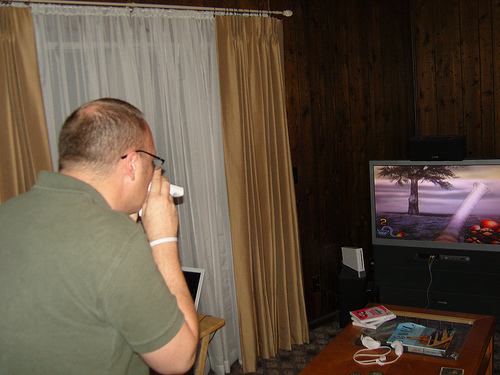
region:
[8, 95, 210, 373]
a man playing wii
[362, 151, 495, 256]
a video game on the TV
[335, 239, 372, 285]
the wii game console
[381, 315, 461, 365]
a closed book on the table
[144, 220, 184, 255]
a white band on wrist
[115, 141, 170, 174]
glasses on the man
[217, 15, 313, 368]
open beige curtains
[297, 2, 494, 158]
dark wood paneled walls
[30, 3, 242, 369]
closed white sheer curtains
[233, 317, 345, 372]
beige and black checkered carpet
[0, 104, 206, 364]
this is a man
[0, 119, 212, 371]
the man is sitted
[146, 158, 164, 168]
the man is wearing spectacles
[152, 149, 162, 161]
the spectacles are back in color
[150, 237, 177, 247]
the man is wearing a wrist band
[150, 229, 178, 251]
the wrist band is white in color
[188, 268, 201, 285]
this is a laptop in front of the man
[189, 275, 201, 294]
the laptop is off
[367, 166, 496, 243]
this is a television screen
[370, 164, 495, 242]
the television screen is on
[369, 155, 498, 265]
The flat screen television.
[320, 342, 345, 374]
The cherry red wood coffee table.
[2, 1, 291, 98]
The white and gold satiny curtains.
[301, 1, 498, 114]
The dark wooden paneled wall.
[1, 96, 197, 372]
A man in a grey shirt.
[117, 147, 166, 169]
The black rimmed glasses.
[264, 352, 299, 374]
The brown designed carpet.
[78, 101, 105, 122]
One small bald spot.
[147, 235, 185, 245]
A white wrist band.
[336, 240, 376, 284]
A video game system.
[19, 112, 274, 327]
man in green shirt playing wii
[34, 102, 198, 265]
man with glasses playing wii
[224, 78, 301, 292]
gold curtains on the window frame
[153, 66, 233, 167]
sheer curtains over night time window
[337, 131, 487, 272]
television screen with game on it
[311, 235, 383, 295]
white box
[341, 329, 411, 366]
wii game controller on table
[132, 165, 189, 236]
wii game controller in man's hand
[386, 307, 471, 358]
magazine on table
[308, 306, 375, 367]
book on brown wooden style table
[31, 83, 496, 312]
a man playing a video game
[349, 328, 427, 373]
a video game controller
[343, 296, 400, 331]
a stack of video games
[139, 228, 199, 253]
a white wrist band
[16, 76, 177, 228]
a man wearing glasses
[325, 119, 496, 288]
a wide screen tv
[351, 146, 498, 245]
a cartoon on tv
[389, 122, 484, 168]
a large black speaker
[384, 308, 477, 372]
a paper back book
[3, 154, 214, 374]
a greenish grey polo shirt